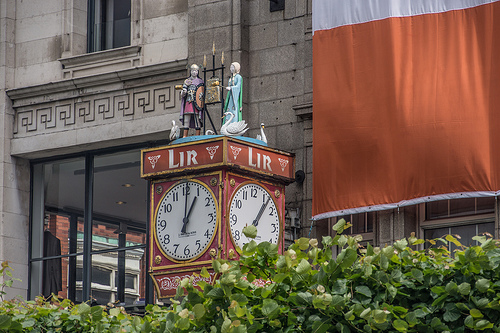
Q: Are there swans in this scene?
A: Yes, there is a swan.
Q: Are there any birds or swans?
A: Yes, there is a swan.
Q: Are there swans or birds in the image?
A: Yes, there is a swan.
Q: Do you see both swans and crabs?
A: No, there is a swan but no crabs.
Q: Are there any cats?
A: No, there are no cats.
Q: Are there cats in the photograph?
A: No, there are no cats.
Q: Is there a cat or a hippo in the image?
A: No, there are no cats or hippos.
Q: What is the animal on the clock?
A: The animal is a swan.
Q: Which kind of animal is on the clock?
A: The animal is a swan.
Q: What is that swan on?
A: The swan is on the clock.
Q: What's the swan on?
A: The swan is on the clock.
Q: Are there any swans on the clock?
A: Yes, there is a swan on the clock.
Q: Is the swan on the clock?
A: Yes, the swan is on the clock.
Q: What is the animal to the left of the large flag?
A: The animal is a swan.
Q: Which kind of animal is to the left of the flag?
A: The animal is a swan.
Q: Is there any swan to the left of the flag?
A: Yes, there is a swan to the left of the flag.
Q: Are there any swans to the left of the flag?
A: Yes, there is a swan to the left of the flag.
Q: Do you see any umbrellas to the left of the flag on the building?
A: No, there is a swan to the left of the flag.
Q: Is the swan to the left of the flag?
A: Yes, the swan is to the left of the flag.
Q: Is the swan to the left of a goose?
A: No, the swan is to the left of the flag.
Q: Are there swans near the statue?
A: Yes, there is a swan near the statue.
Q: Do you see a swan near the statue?
A: Yes, there is a swan near the statue.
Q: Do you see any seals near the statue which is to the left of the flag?
A: No, there is a swan near the statue.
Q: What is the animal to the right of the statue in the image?
A: The animal is a swan.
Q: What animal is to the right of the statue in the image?
A: The animal is a swan.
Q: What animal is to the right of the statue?
A: The animal is a swan.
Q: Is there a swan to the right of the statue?
A: Yes, there is a swan to the right of the statue.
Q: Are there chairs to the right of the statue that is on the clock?
A: No, there is a swan to the right of the statue.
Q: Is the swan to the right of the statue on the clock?
A: Yes, the swan is to the right of the statue.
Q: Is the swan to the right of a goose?
A: No, the swan is to the right of the statue.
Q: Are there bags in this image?
A: No, there are no bags.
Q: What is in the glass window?
A: The jacket is in the window.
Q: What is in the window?
A: The jacket is in the window.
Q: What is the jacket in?
A: The jacket is in the window.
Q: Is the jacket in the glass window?
A: Yes, the jacket is in the window.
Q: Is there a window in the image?
A: Yes, there is a window.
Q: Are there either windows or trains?
A: Yes, there is a window.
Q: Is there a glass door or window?
A: Yes, there is a glass window.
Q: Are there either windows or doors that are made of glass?
A: Yes, the window is made of glass.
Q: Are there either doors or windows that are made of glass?
A: Yes, the window is made of glass.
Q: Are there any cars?
A: No, there are no cars.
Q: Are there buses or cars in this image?
A: No, there are no cars or buses.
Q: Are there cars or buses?
A: No, there are no cars or buses.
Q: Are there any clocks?
A: Yes, there is a clock.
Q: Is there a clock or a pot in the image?
A: Yes, there is a clock.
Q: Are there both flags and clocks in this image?
A: Yes, there are both a clock and a flag.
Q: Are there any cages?
A: No, there are no cages.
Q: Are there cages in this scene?
A: No, there are no cages.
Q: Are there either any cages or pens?
A: No, there are no cages or pens.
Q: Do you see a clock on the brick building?
A: Yes, there is a clock on the building.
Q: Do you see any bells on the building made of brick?
A: No, there is a clock on the building.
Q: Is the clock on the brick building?
A: Yes, the clock is on the building.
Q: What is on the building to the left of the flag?
A: The clock is on the tower.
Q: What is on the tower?
A: The clock is on the tower.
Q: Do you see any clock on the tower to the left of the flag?
A: Yes, there is a clock on the tower.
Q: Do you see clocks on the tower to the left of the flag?
A: Yes, there is a clock on the tower.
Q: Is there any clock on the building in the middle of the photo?
A: Yes, there is a clock on the tower.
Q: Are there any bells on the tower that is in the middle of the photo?
A: No, there is a clock on the tower.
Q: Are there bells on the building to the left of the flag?
A: No, there is a clock on the tower.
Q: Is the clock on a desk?
A: No, the clock is on the tower.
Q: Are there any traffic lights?
A: No, there are no traffic lights.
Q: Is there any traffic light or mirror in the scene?
A: No, there are no traffic lights or mirrors.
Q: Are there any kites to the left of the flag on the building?
A: No, there is a statue to the left of the flag.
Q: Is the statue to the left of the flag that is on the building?
A: Yes, the statue is to the left of the flag.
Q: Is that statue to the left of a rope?
A: No, the statue is to the left of the flag.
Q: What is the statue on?
A: The statue is on the clock.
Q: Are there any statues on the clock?
A: Yes, there is a statue on the clock.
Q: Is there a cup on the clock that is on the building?
A: No, there is a statue on the clock.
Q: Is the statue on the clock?
A: Yes, the statue is on the clock.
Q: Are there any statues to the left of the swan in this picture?
A: Yes, there is a statue to the left of the swan.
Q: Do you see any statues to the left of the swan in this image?
A: Yes, there is a statue to the left of the swan.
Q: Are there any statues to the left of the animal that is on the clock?
A: Yes, there is a statue to the left of the swan.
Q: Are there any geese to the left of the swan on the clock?
A: No, there is a statue to the left of the swan.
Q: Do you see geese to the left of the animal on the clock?
A: No, there is a statue to the left of the swan.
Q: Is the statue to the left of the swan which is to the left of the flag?
A: Yes, the statue is to the left of the swan.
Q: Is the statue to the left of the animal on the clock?
A: Yes, the statue is to the left of the swan.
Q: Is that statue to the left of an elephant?
A: No, the statue is to the left of the swan.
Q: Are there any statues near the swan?
A: Yes, there is a statue near the swan.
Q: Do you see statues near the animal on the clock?
A: Yes, there is a statue near the swan.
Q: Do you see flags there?
A: Yes, there is a flag.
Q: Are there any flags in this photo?
A: Yes, there is a flag.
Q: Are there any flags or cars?
A: Yes, there is a flag.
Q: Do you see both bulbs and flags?
A: No, there is a flag but no light bulbs.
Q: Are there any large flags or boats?
A: Yes, there is a large flag.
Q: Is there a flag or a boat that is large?
A: Yes, the flag is large.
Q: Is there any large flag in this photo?
A: Yes, there is a large flag.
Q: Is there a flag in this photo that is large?
A: Yes, there is a flag that is large.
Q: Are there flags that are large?
A: Yes, there is a flag that is large.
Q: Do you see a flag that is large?
A: Yes, there is a flag that is large.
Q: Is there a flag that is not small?
A: Yes, there is a large flag.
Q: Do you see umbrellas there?
A: No, there are no umbrellas.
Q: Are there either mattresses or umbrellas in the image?
A: No, there are no umbrellas or mattresses.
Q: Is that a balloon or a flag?
A: That is a flag.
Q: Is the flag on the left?
A: No, the flag is on the right of the image.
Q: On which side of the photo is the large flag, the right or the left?
A: The flag is on the right of the image.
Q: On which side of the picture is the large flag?
A: The flag is on the right of the image.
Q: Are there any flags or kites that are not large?
A: No, there is a flag but it is large.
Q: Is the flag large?
A: Yes, the flag is large.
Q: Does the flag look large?
A: Yes, the flag is large.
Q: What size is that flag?
A: The flag is large.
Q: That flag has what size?
A: The flag is large.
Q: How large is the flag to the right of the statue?
A: The flag is large.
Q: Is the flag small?
A: No, the flag is large.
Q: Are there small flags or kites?
A: No, there is a flag but it is large.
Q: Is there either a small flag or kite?
A: No, there is a flag but it is large.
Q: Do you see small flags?
A: No, there is a flag but it is large.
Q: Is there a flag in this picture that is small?
A: No, there is a flag but it is large.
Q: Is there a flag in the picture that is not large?
A: No, there is a flag but it is large.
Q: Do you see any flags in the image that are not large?
A: No, there is a flag but it is large.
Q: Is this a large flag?
A: Yes, this is a large flag.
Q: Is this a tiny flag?
A: No, this is a large flag.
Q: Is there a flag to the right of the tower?
A: Yes, there is a flag to the right of the tower.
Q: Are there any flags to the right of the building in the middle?
A: Yes, there is a flag to the right of the tower.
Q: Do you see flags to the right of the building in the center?
A: Yes, there is a flag to the right of the tower.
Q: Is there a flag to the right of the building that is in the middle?
A: Yes, there is a flag to the right of the tower.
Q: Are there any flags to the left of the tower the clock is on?
A: No, the flag is to the right of the tower.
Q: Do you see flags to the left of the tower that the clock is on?
A: No, the flag is to the right of the tower.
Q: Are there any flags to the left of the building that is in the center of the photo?
A: No, the flag is to the right of the tower.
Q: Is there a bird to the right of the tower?
A: No, there is a flag to the right of the tower.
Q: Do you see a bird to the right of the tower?
A: No, there is a flag to the right of the tower.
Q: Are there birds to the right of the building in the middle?
A: No, there is a flag to the right of the tower.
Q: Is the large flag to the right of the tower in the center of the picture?
A: Yes, the flag is to the right of the tower.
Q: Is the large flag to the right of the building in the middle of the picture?
A: Yes, the flag is to the right of the tower.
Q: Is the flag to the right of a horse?
A: No, the flag is to the right of the tower.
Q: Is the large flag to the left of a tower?
A: No, the flag is to the right of a tower.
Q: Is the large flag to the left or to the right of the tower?
A: The flag is to the right of the tower.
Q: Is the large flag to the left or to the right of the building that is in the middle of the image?
A: The flag is to the right of the tower.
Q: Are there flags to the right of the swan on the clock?
A: Yes, there is a flag to the right of the swan.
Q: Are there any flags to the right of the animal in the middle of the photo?
A: Yes, there is a flag to the right of the swan.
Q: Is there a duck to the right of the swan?
A: No, there is a flag to the right of the swan.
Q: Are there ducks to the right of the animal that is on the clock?
A: No, there is a flag to the right of the swan.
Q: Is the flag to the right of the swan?
A: Yes, the flag is to the right of the swan.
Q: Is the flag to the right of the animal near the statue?
A: Yes, the flag is to the right of the swan.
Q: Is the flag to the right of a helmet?
A: No, the flag is to the right of the swan.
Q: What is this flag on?
A: The flag is on the building.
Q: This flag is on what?
A: The flag is on the building.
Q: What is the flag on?
A: The flag is on the building.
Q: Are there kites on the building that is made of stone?
A: No, there is a flag on the building.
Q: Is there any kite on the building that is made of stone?
A: No, there is a flag on the building.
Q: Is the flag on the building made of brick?
A: Yes, the flag is on the building.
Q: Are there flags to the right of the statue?
A: Yes, there is a flag to the right of the statue.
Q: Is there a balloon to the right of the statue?
A: No, there is a flag to the right of the statue.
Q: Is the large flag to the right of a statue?
A: Yes, the flag is to the right of a statue.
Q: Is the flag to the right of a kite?
A: No, the flag is to the right of a statue.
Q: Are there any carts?
A: No, there are no carts.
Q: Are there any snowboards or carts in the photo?
A: No, there are no carts or snowboards.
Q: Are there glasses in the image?
A: No, there are no glasses.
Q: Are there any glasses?
A: No, there are no glasses.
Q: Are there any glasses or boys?
A: No, there are no glasses or boys.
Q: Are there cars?
A: No, there are no cars.